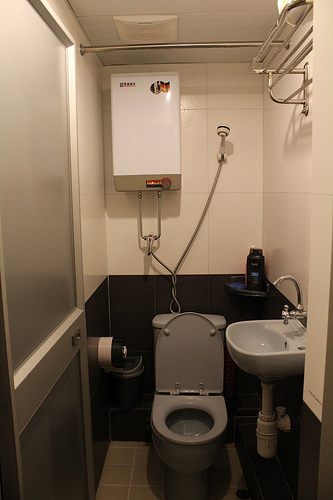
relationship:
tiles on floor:
[120, 451, 169, 481] [95, 437, 292, 498]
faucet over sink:
[268, 270, 307, 328] [219, 268, 318, 386]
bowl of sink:
[227, 321, 291, 356] [214, 283, 318, 385]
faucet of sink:
[268, 270, 307, 328] [225, 272, 310, 400]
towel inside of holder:
[98, 330, 126, 372] [95, 328, 134, 366]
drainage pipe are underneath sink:
[255, 387, 281, 461] [225, 305, 306, 376]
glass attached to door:
[2, 21, 81, 327] [9, 18, 105, 495]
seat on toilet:
[150, 389, 228, 447] [149, 310, 226, 490]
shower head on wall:
[215, 121, 232, 160] [102, 59, 263, 439]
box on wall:
[105, 66, 186, 193] [102, 59, 263, 439]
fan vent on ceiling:
[112, 13, 179, 46] [66, 0, 279, 67]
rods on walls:
[77, 0, 315, 118] [0, 0, 333, 496]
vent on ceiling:
[112, 14, 180, 45] [66, 0, 279, 67]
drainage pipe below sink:
[255, 387, 281, 461] [226, 316, 307, 388]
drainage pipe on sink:
[255, 387, 291, 461] [226, 314, 308, 370]